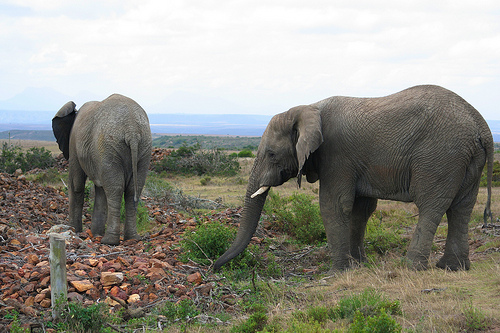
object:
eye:
[269, 153, 276, 158]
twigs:
[145, 280, 233, 318]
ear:
[296, 108, 324, 188]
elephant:
[51, 93, 151, 245]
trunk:
[213, 170, 270, 273]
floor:
[75, 103, 147, 130]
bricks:
[83, 255, 170, 308]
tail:
[480, 132, 493, 226]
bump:
[314, 95, 356, 110]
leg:
[405, 193, 451, 259]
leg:
[444, 189, 478, 260]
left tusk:
[250, 186, 270, 199]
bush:
[177, 216, 236, 264]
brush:
[142, 183, 219, 209]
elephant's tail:
[125, 134, 142, 202]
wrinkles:
[400, 122, 420, 195]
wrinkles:
[76, 128, 93, 172]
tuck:
[251, 186, 270, 199]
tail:
[125, 131, 142, 203]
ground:
[0, 111, 500, 333]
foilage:
[153, 144, 242, 177]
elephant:
[213, 85, 492, 274]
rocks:
[0, 147, 319, 333]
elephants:
[51, 84, 493, 276]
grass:
[29, 170, 499, 333]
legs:
[318, 173, 377, 271]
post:
[47, 233, 66, 323]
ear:
[52, 101, 77, 161]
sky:
[0, 0, 500, 122]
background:
[0, 0, 500, 145]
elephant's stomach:
[356, 169, 414, 202]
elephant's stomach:
[80, 161, 103, 187]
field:
[0, 134, 496, 332]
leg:
[349, 197, 377, 265]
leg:
[318, 173, 357, 266]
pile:
[477, 223, 500, 238]